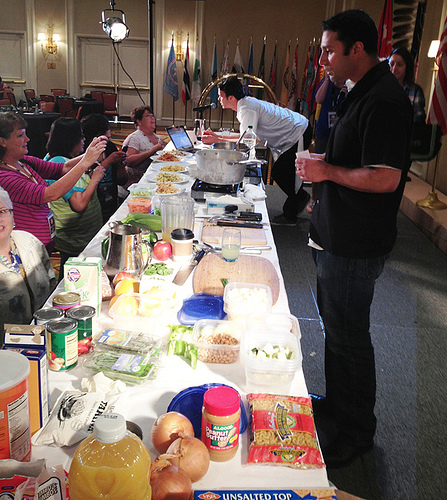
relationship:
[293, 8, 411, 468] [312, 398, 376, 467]
man wearing shoes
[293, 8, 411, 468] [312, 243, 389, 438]
man wearing pants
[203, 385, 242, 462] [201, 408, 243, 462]
jar full of peanuts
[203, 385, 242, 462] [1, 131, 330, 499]
jar on table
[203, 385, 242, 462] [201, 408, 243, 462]
jar has peanuts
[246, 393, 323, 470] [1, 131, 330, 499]
pasta on table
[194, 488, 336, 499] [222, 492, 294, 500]
box has white printing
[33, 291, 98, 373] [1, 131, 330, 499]
cans are on table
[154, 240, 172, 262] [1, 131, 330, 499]
apple on table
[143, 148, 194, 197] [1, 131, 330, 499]
plates are on a table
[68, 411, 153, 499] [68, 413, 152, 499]
bottle full of orange juice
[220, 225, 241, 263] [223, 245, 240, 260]
glass has juice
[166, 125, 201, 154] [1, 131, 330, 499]
laptop on table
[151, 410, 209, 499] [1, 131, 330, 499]
onions are on table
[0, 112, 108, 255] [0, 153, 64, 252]
woman wearing a striped shirt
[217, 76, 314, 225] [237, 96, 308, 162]
person wearing a white shirt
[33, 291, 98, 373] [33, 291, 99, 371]
cans have food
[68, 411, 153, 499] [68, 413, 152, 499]
bottle has juice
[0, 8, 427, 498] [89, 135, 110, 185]
people are taking pictures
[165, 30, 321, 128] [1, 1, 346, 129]
flags are near a wall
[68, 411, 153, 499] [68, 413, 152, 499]
bottle of orange juice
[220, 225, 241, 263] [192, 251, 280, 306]
glass on cutting board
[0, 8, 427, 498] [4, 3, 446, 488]
people in room